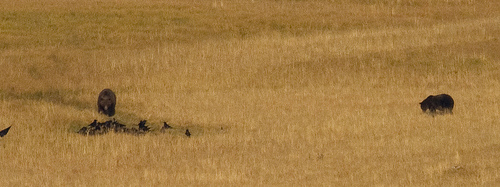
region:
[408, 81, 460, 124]
cow is color black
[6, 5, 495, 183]
cows on a field of dry grass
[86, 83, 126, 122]
cow is eating dry grass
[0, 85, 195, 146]
black birds in front a cow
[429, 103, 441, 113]
front legs of cow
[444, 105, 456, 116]
back legs of cow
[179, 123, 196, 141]
a black bird on dry grass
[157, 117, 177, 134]
a black bird on dry grass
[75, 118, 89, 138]
a black bird on dry grass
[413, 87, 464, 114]
an animal in the field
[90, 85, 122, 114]
an animal in the field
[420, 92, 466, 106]
a black animal in the field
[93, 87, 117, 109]
a black animal in the field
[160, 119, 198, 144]
birds in the field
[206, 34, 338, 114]
yellow dried grass in the field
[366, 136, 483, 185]
yellow dried grass in the field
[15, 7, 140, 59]
yellow dried grass in the field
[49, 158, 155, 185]
yellow dried grass in the field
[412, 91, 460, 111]
an animal eating grass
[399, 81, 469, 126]
small bear standing in field of grass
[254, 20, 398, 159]
field covered in light brown grass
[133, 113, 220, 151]
group of black birds standing in field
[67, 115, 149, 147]
carcass of dead animal laying in grass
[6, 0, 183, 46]
light green grass growing in distance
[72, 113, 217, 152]
birds swarming dead body of animal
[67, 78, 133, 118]
small bear approaching dead animal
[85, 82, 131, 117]
brown bear standing in field of brown grass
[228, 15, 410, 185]
ground covered in tall brown grass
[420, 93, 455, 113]
Bear standing in field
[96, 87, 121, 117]
Bear standing in tan field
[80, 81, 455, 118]
Two bears in a field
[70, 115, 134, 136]
Pile of debris on field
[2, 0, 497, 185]
Large open tan colored field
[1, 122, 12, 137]
Bird pecking at field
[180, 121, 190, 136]
Bird standing in field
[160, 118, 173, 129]
Bird in field watching bear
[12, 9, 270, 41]
Greenish gold part of field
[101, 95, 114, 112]
Bear's face on body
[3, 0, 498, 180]
an open field covered with grass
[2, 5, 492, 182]
field is covered with dry grass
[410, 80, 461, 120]
a cow is color black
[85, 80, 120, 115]
a cow is color black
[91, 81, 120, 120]
a cow is eating dry grass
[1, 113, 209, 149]
black birds on a dry grass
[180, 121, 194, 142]
black bird on dry grass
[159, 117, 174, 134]
black bird on dry grass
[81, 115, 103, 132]
black bird on dry grass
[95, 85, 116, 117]
large brown bear in a tan field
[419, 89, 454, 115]
large brown bear in a tan field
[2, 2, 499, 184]
field of dry brown grass and weeds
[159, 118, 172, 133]
black bird sitting in a field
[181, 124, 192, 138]
black bird sitting in a field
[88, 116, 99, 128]
black bird sitting in a field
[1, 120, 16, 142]
black bird sitting in a field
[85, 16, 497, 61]
strip of light brown grass through the field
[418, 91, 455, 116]
brown bear facing to the left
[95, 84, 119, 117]
brown bear facing the camera